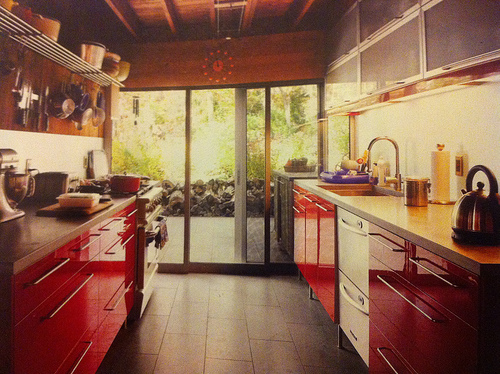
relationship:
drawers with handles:
[1, 215, 166, 371] [23, 262, 99, 323]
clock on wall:
[190, 39, 242, 100] [128, 30, 331, 128]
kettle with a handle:
[441, 159, 499, 244] [454, 159, 495, 195]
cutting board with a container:
[41, 195, 117, 222] [54, 191, 100, 212]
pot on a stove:
[104, 175, 144, 199] [105, 182, 179, 320]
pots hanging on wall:
[3, 50, 115, 151] [1, 35, 122, 191]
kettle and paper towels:
[451, 165, 500, 245] [427, 137, 457, 204]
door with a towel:
[137, 201, 162, 291] [147, 210, 176, 257]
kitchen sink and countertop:
[319, 173, 408, 203] [263, 171, 497, 278]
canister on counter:
[401, 166, 435, 216] [328, 186, 498, 286]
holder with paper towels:
[427, 137, 452, 162] [418, 137, 474, 220]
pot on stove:
[104, 175, 144, 199] [81, 175, 190, 265]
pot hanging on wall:
[39, 82, 80, 125] [1, 0, 123, 222]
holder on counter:
[315, 160, 371, 184] [293, 171, 498, 283]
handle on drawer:
[375, 272, 440, 323] [365, 249, 489, 373]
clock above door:
[198, 45, 238, 86] [182, 82, 269, 272]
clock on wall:
[198, 45, 238, 86] [94, 25, 328, 89]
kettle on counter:
[451, 165, 500, 245] [328, 186, 498, 286]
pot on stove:
[102, 169, 145, 197] [64, 169, 157, 203]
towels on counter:
[424, 147, 449, 207] [336, 186, 497, 280]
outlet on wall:
[451, 152, 471, 174] [343, 70, 498, 215]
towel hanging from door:
[156, 218, 173, 250] [137, 201, 162, 291]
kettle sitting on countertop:
[451, 165, 500, 245] [394, 207, 440, 235]